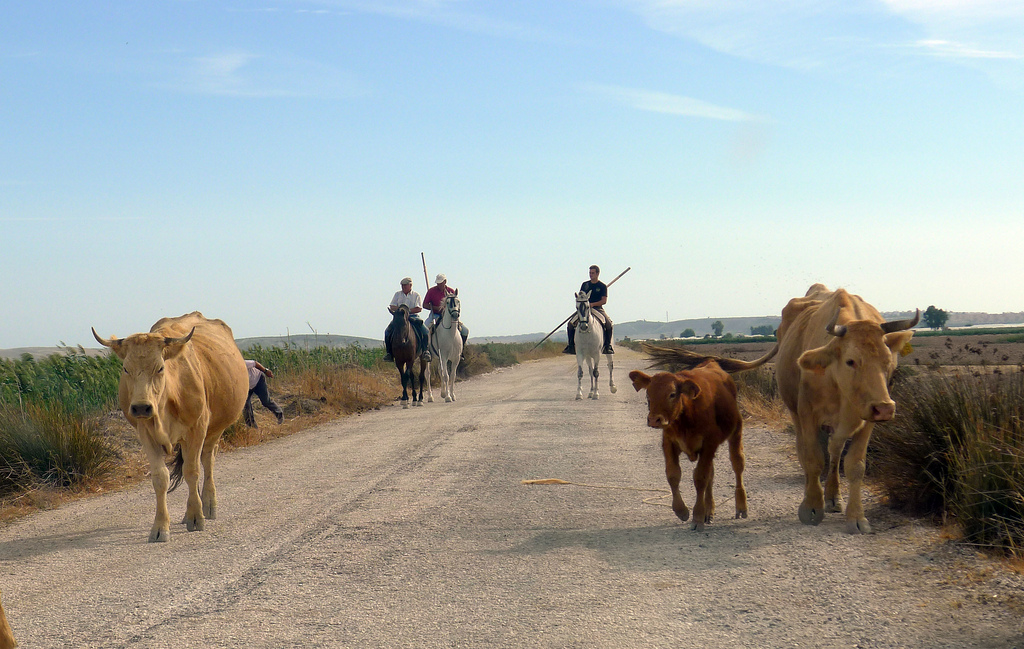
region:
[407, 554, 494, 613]
sand is brown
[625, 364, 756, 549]
a calf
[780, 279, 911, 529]
a cow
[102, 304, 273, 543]
a tanned cow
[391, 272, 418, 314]
person on a horse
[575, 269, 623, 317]
a man on a horse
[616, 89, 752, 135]
a cloud in the sky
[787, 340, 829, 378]
the cows ear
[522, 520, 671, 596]
shadow on the ground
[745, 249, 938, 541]
brown animal with horns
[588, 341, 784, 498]
dark brown animal next to bigger one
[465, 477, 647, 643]
shadow on the ground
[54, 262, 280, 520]
light cow on the ground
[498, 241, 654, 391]
man holding a long object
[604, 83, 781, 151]
cloud in the sky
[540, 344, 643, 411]
legs of the horse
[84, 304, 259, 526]
brown cow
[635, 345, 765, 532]
brown cow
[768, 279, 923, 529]
brown cow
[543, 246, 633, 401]
man riding horse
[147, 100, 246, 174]
white clouds in blue sky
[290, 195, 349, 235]
white clouds in blue sky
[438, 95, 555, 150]
white clouds in the blue sky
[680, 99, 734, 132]
white clouds in the blue sky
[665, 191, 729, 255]
white clouds in the blue sky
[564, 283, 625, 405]
a white horse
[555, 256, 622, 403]
a man on a white horse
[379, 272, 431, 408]
man on a brown horse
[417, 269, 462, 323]
man wearing a red shirt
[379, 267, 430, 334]
a man wearing a white shirt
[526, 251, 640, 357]
man carrying a big stick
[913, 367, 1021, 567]
a green bush beside the road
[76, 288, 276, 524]
brown cow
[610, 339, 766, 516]
cow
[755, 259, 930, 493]
brown cow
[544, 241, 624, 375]
man riding white horse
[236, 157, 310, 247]
white clouds in blue sky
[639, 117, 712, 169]
white clouds in blue sky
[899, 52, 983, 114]
white clouds in the blue sky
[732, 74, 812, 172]
white clouds in the blue sky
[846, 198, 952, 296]
white clouds in the blue sky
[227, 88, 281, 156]
white clouds in the blue sky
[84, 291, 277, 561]
brown cow walking on dirt road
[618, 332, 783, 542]
brown cow walking on dirt road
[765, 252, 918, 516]
brown cow walking on dirt road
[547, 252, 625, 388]
man riding horse on dirt road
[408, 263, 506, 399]
man riding horse on dirt road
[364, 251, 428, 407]
man riding horse on dirt road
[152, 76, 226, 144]
white clouds in blue sky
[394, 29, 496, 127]
white clouds in blue sky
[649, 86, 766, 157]
white clouds in blue sky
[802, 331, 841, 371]
cow has an ear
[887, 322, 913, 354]
cow has an ear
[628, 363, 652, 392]
cow has an ear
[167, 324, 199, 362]
cow has an ear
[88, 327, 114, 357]
cow has an ear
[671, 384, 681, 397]
cow has an eye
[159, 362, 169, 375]
cow has an eye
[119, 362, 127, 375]
cow has an eye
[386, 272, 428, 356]
person on a dark colored horse